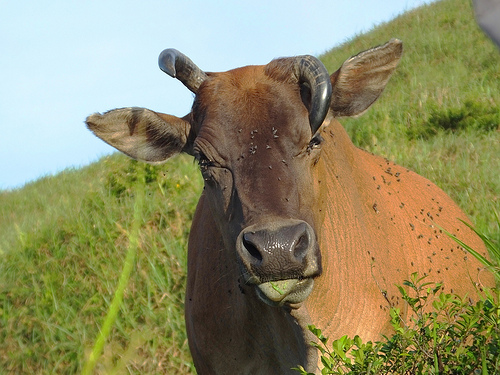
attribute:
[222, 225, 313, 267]
nose — nostril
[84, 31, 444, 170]
cow — brown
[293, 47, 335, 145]
cow's horn — facingup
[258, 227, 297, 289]
cow's — wet snout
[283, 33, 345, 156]
horn growing — into head